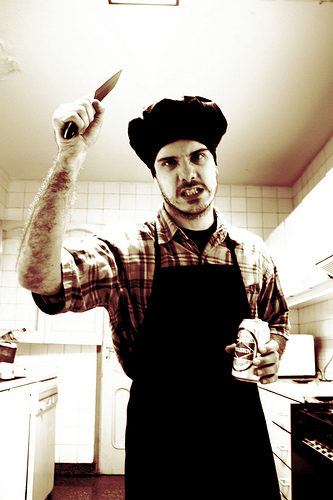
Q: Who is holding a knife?
A: Man with chef hat.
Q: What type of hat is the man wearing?
A: Chef hat.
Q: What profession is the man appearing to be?
A: Chef.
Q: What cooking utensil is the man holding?
A: Knife.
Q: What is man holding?
A: Knife.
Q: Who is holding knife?
A: A man.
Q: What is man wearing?
A: Apron.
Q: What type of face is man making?
A: Scowling.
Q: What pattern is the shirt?
A: Plaid.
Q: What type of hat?
A: Chef.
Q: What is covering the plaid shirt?
A: An apron.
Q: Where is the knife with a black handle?
A: Raise in air.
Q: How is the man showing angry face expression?
A: With eyes and mouth.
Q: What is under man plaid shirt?
A: Black tee shirt.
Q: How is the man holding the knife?
A: Right hand.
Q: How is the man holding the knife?
A: With a fist.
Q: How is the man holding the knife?
A: The handle.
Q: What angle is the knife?
A: Backward.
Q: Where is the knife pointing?
A: Toward the ceiling.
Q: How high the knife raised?
A: Above man head.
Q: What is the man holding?
A: A knife.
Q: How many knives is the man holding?
A: One.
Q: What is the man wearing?
A: An apron.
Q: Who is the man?
A: A chef.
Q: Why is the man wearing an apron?
A: He was cooking.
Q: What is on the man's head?
A: A chef's hat.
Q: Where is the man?
A: A kitchen.